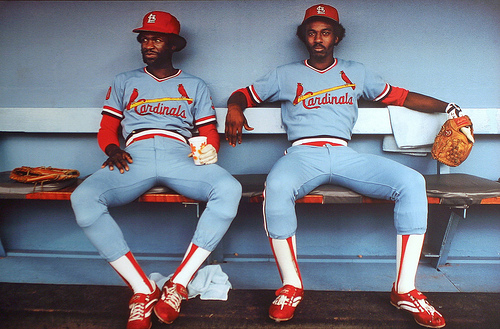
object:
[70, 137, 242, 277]
pants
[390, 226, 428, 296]
red sock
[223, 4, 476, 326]
ball player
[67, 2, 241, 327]
ball player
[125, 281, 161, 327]
shoes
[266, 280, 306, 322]
shoes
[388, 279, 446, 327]
shoes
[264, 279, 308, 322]
foot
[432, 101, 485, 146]
glove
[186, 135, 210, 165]
cup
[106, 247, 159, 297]
sock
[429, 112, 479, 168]
mitt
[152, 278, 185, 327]
shoe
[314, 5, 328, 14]
yes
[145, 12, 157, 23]
yes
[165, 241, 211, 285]
sock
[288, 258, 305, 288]
line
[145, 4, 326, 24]
white letter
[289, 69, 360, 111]
logo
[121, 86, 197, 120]
logo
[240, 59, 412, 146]
jersey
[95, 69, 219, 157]
jersey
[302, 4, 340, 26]
hat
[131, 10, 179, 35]
hat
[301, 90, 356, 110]
cardinals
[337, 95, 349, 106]
letters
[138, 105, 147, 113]
letters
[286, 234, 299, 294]
part